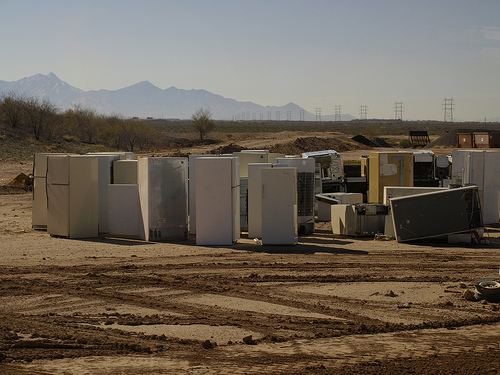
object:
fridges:
[139, 157, 188, 242]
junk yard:
[0, 120, 500, 370]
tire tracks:
[15, 278, 294, 340]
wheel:
[475, 281, 500, 299]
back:
[390, 186, 478, 243]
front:
[47, 156, 69, 237]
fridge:
[45, 154, 99, 238]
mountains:
[0, 71, 116, 117]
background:
[0, 0, 500, 130]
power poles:
[441, 97, 455, 122]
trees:
[1, 92, 27, 126]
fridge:
[196, 157, 241, 245]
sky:
[1, 0, 500, 123]